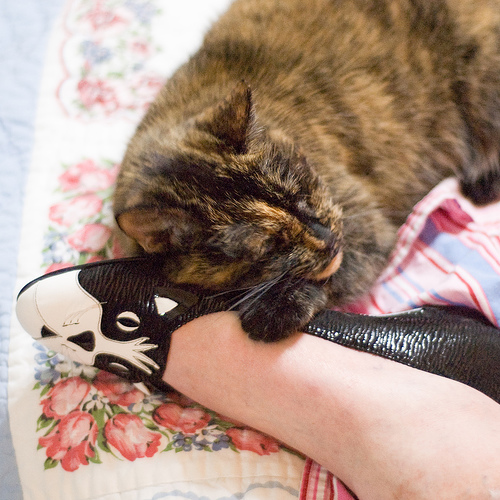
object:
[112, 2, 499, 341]
cat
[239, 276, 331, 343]
paw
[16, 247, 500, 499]
foot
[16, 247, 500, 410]
shoe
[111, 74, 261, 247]
ears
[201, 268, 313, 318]
whiskers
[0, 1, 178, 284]
sheet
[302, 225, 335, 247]
nose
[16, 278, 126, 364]
tip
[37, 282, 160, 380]
face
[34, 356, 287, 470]
roses